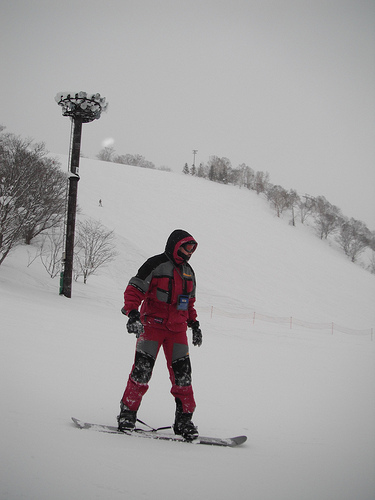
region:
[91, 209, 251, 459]
boarder in the snow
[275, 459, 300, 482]
patch of white snow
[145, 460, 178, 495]
patch of white snow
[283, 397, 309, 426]
patch of white snow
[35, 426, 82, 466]
patch of white snow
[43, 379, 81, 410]
patch of white snow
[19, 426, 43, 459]
patch of white snow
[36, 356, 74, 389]
patch of white snow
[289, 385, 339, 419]
patch of white snow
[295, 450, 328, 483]
patch of white snow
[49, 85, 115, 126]
a tower on ice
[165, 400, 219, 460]
shoe of the person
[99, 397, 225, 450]
two shoes of the person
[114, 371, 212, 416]
a red covering to leg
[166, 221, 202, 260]
face covered with cloth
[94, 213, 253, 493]
a man in the ice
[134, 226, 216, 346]
a man wearing jacket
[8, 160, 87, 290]
a part of the trees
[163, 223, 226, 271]
the head of a man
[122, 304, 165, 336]
the hand of a man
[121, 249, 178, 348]
the arm of a man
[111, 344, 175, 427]
the leg of a man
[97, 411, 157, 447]
the foot of a man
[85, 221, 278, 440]
a man on a snowboard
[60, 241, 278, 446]
a man in the snow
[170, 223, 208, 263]
a man wearing goggles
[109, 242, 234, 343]
a man wearing a coat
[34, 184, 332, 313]
a pole hear a man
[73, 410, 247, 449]
a gray skiboard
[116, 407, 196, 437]
a couple of black boots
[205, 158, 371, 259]
several small trees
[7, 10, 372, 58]
a gray sky in the background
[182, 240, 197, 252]
the protective goggles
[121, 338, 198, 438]
the two legs of the man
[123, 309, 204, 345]
a couple of black gloves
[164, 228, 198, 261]
the head of the skier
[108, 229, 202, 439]
a man in a red and black suit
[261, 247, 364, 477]
a lot of snow in the field